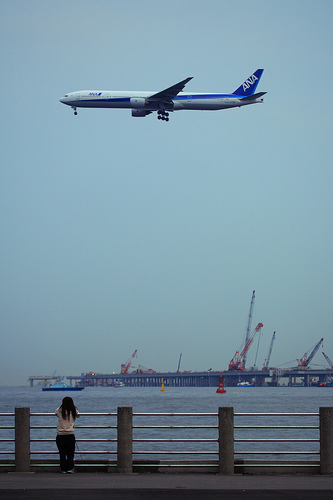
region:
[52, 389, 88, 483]
Girl, leaning on rail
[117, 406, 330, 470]
Metal and wood railing near water.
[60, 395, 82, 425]
Long brown hair on girl.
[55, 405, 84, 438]
White shirt on girl.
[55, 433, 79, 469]
Black pants on girl.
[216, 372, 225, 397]
Buoy on calm water.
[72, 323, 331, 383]
Long deck with giant cranes.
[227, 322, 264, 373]
Orange and white crane.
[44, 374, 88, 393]
Long blue boat passing deck.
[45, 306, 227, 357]
Dull, blue sky overhead.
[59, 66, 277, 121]
blue and grey plane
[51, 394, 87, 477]
short woman barely taller than railing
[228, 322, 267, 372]
huge red crane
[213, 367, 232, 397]
a red buoy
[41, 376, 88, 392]
a small boat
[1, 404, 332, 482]
railing to prevent people from falling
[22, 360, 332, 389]
pier being worked on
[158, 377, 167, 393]
a yellow buoy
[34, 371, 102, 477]
a woman looking at the ocean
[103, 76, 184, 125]
wheels out on a plane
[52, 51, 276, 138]
Blue and white plane flying.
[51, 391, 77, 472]
Girl in white shirt fishing.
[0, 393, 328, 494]
Boardwalk with railing on the waterfront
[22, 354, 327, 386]
Bridge in the middle of being built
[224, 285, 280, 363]
Construction equipment building bridge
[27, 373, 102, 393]
Blue boat on the water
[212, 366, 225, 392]
Red buoy on the water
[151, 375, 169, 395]
Yellow buoy on the water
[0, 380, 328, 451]
Large body of water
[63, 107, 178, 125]
Plane landing gear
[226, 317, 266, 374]
Tall orange crane machine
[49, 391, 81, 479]
Young woman looking at water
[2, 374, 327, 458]
Large body of water like an ocean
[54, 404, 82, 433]
White short sleeve shirt worn by woman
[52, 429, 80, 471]
black sweatpants worn by woman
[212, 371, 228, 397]
Red dinghy floating in water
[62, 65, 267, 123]
Flying blue and white plane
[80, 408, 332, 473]
Post and bars next to water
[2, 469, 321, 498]
grey sidewalk woman is standing on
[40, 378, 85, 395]
white and blue boat in water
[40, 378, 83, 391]
Blue ship in the water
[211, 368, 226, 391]
Red buoy floating in water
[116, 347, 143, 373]
Red crane working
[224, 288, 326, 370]
Many different cranes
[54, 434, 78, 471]
Dark pants on woman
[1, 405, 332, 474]
Guard rail protecting bystanders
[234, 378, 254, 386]
Smaller blue and white boat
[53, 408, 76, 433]
White sweatshirt on woman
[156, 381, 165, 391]
Orange buoy floating in the water